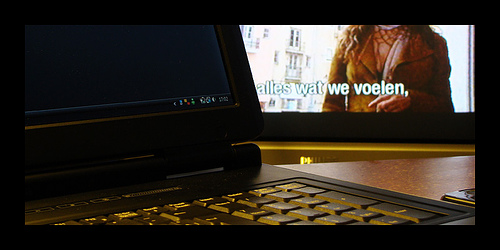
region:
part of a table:
[400, 160, 425, 187]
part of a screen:
[356, 43, 393, 87]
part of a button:
[294, 201, 310, 219]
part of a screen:
[142, 65, 177, 108]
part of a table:
[405, 163, 423, 190]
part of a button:
[277, 210, 289, 221]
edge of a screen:
[404, 109, 421, 126]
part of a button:
[240, 195, 257, 207]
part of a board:
[276, 153, 314, 210]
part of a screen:
[333, 55, 383, 127]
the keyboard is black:
[188, 158, 282, 222]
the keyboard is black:
[198, 132, 310, 244]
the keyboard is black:
[236, 183, 315, 242]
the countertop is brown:
[347, 170, 467, 207]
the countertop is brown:
[297, 129, 384, 191]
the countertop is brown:
[379, 138, 443, 195]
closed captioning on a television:
[256, 23, 483, 138]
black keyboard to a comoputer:
[58, 167, 457, 227]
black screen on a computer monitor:
[23, 15, 274, 178]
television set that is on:
[245, 15, 477, 150]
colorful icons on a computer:
[161, 83, 255, 135]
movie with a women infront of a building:
[243, 23, 476, 129]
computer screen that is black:
[26, 16, 266, 220]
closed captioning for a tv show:
[253, 65, 417, 109]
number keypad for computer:
[211, 179, 437, 226]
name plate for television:
[286, 143, 348, 168]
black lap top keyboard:
[32, 183, 465, 228]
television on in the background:
[252, 8, 499, 139]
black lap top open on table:
[25, 23, 473, 235]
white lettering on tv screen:
[246, 65, 412, 98]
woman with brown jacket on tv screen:
[323, 19, 460, 114]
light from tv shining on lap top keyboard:
[150, 169, 408, 227]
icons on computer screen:
[160, 90, 233, 120]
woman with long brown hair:
[321, 24, 446, 60]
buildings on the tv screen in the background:
[254, 13, 346, 118]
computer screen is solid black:
[37, 30, 213, 107]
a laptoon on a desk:
[12, 15, 465, 227]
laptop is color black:
[1, 4, 469, 223]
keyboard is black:
[2, 179, 455, 233]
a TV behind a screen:
[237, 22, 477, 146]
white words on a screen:
[256, 66, 410, 108]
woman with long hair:
[319, 25, 452, 121]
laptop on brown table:
[6, 140, 471, 225]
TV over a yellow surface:
[246, 18, 473, 158]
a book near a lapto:
[294, 155, 478, 229]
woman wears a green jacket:
[312, 25, 464, 114]